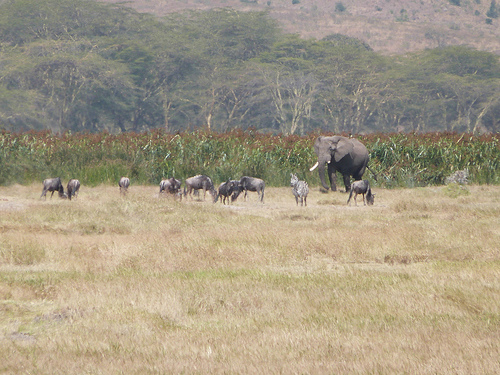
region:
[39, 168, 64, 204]
this is a water buck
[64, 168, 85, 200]
this is a water buck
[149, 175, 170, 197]
this is a water buck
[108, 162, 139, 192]
this is a water buck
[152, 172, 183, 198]
this is a water buck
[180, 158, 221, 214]
this is a water buck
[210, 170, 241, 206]
this is a water buck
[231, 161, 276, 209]
this is a water buck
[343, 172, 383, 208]
this is a water buck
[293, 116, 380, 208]
this is an elephant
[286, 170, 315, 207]
a black and white zebra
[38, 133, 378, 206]
a group of different kinds of animals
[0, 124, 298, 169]
a patch of very tall green and brown grass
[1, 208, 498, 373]
mostly dead brown grass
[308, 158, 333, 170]
a pair of white tusks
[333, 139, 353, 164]
a big floppy ear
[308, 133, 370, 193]
a big grey elephant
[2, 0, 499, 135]
a bunch of trees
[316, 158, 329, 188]
a grey elephant trunk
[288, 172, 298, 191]
the head of a zebra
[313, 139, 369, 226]
large elephant standing in dry grass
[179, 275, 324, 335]
plains with long dry grass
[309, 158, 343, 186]
elephant has broken tusk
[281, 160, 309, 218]
zebra is running in grass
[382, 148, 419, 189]
tall green grass behind elephant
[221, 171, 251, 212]
gray gazelle near zebra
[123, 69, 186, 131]
tall green trees in distance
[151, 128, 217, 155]
tops of green grass is brown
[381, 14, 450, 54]
green and brown plains in distance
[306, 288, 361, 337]
green and brown grass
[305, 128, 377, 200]
An elephant on the Savanah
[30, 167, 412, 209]
A herd of animals near an elephant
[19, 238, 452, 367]
Brown grass in a field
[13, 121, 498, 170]
Plants growing behind an elephant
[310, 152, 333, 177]
Tusks on an elephant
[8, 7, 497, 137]
Large trees in the distance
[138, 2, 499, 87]
A hillside beyond the trees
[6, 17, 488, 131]
A forest in the background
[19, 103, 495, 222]
Animals in a field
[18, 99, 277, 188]
Corn growing in a field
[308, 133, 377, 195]
a large grey elephant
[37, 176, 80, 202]
two wildabeasts grazing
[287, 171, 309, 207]
a zebra looking away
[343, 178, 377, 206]
a zebra grazing grass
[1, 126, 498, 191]
tall grasses with orange flowers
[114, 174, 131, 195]
the rear end of an animal in the grass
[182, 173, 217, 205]
an animal with head down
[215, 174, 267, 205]
two herd animals facing each other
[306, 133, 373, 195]
an elephant with ivory tusks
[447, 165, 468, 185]
a zebra slipping into the tall grass